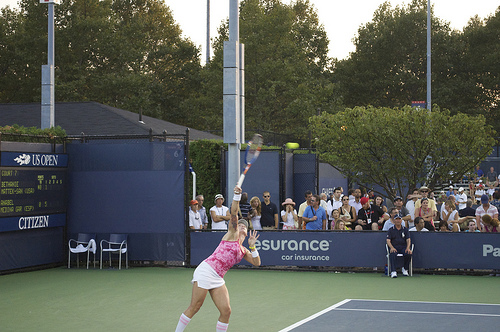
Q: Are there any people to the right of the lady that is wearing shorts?
A: Yes, there is a person to the right of the lady.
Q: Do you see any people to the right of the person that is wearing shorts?
A: Yes, there is a person to the right of the lady.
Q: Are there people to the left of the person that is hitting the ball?
A: No, the person is to the right of the lady.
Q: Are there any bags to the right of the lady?
A: No, there is a person to the right of the lady.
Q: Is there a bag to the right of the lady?
A: No, there is a person to the right of the lady.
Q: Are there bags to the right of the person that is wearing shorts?
A: No, there is a person to the right of the lady.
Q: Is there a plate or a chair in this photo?
A: Yes, there is a chair.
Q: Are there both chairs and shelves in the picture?
A: No, there is a chair but no shelves.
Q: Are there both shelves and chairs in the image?
A: No, there is a chair but no shelves.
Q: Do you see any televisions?
A: No, there are no televisions.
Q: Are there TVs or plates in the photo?
A: No, there are no TVs or plates.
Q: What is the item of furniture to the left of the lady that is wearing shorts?
A: The piece of furniture is a chair.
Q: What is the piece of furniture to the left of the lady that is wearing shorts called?
A: The piece of furniture is a chair.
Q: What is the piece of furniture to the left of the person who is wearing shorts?
A: The piece of furniture is a chair.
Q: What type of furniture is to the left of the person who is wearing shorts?
A: The piece of furniture is a chair.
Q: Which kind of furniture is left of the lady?
A: The piece of furniture is a chair.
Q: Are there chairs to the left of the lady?
A: Yes, there is a chair to the left of the lady.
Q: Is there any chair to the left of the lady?
A: Yes, there is a chair to the left of the lady.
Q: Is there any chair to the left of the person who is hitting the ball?
A: Yes, there is a chair to the left of the lady.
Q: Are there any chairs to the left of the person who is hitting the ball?
A: Yes, there is a chair to the left of the lady.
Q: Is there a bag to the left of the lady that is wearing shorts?
A: No, there is a chair to the left of the lady.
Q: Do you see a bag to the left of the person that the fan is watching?
A: No, there is a chair to the left of the lady.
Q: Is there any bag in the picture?
A: No, there are no bags.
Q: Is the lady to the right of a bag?
A: No, the lady is to the right of a chair.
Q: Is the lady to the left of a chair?
A: No, the lady is to the right of a chair.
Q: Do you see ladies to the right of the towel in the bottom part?
A: Yes, there is a lady to the right of the towel.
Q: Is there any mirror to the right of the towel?
A: No, there is a lady to the right of the towel.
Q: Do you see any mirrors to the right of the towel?
A: No, there is a lady to the right of the towel.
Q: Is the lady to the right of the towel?
A: Yes, the lady is to the right of the towel.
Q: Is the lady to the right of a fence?
A: No, the lady is to the right of the towel.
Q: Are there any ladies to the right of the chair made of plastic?
A: Yes, there is a lady to the right of the chair.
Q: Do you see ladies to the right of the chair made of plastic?
A: Yes, there is a lady to the right of the chair.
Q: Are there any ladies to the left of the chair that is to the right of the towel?
A: No, the lady is to the right of the chair.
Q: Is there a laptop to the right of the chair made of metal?
A: No, there is a lady to the right of the chair.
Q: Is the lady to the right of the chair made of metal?
A: Yes, the lady is to the right of the chair.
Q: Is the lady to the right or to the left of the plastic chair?
A: The lady is to the right of the chair.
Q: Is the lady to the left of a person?
A: Yes, the lady is to the left of a person.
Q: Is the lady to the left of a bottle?
A: No, the lady is to the left of a person.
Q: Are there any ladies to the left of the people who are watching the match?
A: Yes, there is a lady to the left of the people.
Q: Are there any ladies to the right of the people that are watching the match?
A: No, the lady is to the left of the people.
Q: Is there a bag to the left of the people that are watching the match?
A: No, there is a lady to the left of the people.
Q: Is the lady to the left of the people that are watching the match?
A: Yes, the lady is to the left of the people.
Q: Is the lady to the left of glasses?
A: No, the lady is to the left of the people.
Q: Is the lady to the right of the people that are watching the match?
A: No, the lady is to the left of the people.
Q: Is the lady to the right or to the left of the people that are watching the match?
A: The lady is to the left of the people.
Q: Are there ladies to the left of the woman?
A: Yes, there is a lady to the left of the woman.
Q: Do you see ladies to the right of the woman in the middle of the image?
A: No, the lady is to the left of the woman.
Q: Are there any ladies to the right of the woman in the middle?
A: No, the lady is to the left of the woman.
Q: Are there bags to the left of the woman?
A: No, there is a lady to the left of the woman.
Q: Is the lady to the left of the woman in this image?
A: Yes, the lady is to the left of the woman.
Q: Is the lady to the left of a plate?
A: No, the lady is to the left of the woman.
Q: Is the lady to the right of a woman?
A: No, the lady is to the left of a woman.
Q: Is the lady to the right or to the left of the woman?
A: The lady is to the left of the woman.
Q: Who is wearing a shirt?
A: The lady is wearing a shirt.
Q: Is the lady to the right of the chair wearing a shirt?
A: Yes, the lady is wearing a shirt.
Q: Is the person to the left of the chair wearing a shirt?
A: Yes, the lady is wearing a shirt.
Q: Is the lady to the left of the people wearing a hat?
A: No, the lady is wearing a shirt.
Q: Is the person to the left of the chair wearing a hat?
A: No, the lady is wearing a shirt.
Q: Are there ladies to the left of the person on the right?
A: Yes, there is a lady to the left of the person.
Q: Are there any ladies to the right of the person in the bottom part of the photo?
A: No, the lady is to the left of the person.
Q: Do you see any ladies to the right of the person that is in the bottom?
A: No, the lady is to the left of the person.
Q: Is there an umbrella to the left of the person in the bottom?
A: No, there is a lady to the left of the person.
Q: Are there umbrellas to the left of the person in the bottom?
A: No, there is a lady to the left of the person.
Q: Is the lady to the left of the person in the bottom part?
A: Yes, the lady is to the left of the person.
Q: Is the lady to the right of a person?
A: No, the lady is to the left of a person.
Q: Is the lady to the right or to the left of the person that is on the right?
A: The lady is to the left of the person.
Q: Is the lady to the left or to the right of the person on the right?
A: The lady is to the left of the person.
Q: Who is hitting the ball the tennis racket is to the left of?
A: The lady is hitting the ball.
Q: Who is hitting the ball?
A: The lady is hitting the ball.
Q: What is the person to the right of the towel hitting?
A: The lady is hitting the ball.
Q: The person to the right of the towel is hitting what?
A: The lady is hitting the ball.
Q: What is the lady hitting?
A: The lady is hitting the ball.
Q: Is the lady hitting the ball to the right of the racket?
A: Yes, the lady is hitting the ball.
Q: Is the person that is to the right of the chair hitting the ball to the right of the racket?
A: Yes, the lady is hitting the ball.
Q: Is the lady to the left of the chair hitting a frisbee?
A: No, the lady is hitting the ball.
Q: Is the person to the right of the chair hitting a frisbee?
A: No, the lady is hitting the ball.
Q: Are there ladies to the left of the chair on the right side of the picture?
A: Yes, there is a lady to the left of the chair.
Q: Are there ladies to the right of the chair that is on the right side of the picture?
A: No, the lady is to the left of the chair.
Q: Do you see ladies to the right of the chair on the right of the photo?
A: No, the lady is to the left of the chair.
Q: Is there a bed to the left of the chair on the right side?
A: No, there is a lady to the left of the chair.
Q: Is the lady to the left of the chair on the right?
A: Yes, the lady is to the left of the chair.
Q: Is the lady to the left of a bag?
A: No, the lady is to the left of the chair.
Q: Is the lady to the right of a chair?
A: No, the lady is to the left of a chair.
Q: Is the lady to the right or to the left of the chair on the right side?
A: The lady is to the left of the chair.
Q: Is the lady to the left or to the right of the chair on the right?
A: The lady is to the left of the chair.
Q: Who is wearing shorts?
A: The lady is wearing shorts.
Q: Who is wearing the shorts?
A: The lady is wearing shorts.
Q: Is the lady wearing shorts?
A: Yes, the lady is wearing shorts.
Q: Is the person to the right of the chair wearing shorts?
A: Yes, the lady is wearing shorts.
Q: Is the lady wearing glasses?
A: No, the lady is wearing shorts.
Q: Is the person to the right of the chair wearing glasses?
A: No, the lady is wearing shorts.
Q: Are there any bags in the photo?
A: No, there are no bags.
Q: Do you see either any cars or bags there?
A: No, there are no bags or cars.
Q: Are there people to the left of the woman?
A: Yes, there are people to the left of the woman.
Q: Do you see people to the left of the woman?
A: Yes, there are people to the left of the woman.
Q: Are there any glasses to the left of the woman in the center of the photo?
A: No, there are people to the left of the woman.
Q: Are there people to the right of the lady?
A: Yes, there are people to the right of the lady.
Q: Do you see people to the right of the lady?
A: Yes, there are people to the right of the lady.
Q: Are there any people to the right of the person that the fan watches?
A: Yes, there are people to the right of the lady.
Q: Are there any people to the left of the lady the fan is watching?
A: No, the people are to the right of the lady.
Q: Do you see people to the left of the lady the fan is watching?
A: No, the people are to the right of the lady.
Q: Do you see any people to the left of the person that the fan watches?
A: No, the people are to the right of the lady.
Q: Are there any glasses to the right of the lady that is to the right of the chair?
A: No, there are people to the right of the lady.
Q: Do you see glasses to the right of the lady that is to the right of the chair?
A: No, there are people to the right of the lady.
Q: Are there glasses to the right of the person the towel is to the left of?
A: No, there are people to the right of the lady.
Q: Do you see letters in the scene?
A: Yes, there are letters.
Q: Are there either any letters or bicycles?
A: Yes, there are letters.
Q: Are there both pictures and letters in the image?
A: No, there are letters but no pictures.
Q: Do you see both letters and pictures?
A: No, there are letters but no pictures.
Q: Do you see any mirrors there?
A: No, there are no mirrors.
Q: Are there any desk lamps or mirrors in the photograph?
A: No, there are no mirrors or desk lamps.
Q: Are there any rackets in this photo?
A: Yes, there is a racket.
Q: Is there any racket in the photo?
A: Yes, there is a racket.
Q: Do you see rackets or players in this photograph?
A: Yes, there is a racket.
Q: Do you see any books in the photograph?
A: No, there are no books.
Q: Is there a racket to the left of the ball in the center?
A: Yes, there is a racket to the left of the ball.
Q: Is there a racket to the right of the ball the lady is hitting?
A: No, the racket is to the left of the ball.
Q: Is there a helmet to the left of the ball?
A: No, there is a racket to the left of the ball.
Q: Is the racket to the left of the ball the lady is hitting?
A: Yes, the racket is to the left of the ball.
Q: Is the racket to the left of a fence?
A: No, the racket is to the left of the ball.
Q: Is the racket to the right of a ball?
A: No, the racket is to the left of a ball.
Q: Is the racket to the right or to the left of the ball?
A: The racket is to the left of the ball.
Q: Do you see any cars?
A: No, there are no cars.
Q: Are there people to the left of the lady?
A: No, the person is to the right of the lady.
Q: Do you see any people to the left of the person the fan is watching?
A: No, the person is to the right of the lady.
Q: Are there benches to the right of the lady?
A: No, there is a person to the right of the lady.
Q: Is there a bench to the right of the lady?
A: No, there is a person to the right of the lady.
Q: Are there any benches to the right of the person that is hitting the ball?
A: No, there is a person to the right of the lady.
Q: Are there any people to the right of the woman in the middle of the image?
A: Yes, there is a person to the right of the woman.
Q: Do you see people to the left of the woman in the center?
A: No, the person is to the right of the woman.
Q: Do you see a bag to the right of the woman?
A: No, there is a person to the right of the woman.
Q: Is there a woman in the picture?
A: Yes, there is a woman.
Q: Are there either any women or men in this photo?
A: Yes, there is a woman.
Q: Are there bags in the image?
A: No, there are no bags.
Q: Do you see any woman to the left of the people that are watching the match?
A: Yes, there is a woman to the left of the people.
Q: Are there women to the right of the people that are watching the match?
A: No, the woman is to the left of the people.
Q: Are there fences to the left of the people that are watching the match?
A: No, there is a woman to the left of the people.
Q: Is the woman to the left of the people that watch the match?
A: Yes, the woman is to the left of the people.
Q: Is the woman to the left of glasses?
A: No, the woman is to the left of the people.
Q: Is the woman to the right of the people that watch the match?
A: No, the woman is to the left of the people.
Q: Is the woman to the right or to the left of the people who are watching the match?
A: The woman is to the left of the people.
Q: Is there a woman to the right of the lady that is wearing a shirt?
A: Yes, there is a woman to the right of the lady.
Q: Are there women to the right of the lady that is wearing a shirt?
A: Yes, there is a woman to the right of the lady.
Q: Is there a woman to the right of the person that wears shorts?
A: Yes, there is a woman to the right of the lady.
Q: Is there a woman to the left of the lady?
A: No, the woman is to the right of the lady.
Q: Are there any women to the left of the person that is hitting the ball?
A: No, the woman is to the right of the lady.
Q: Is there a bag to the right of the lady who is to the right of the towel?
A: No, there is a woman to the right of the lady.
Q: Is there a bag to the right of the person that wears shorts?
A: No, there is a woman to the right of the lady.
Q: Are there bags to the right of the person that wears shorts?
A: No, there is a woman to the right of the lady.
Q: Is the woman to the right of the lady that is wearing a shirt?
A: Yes, the woman is to the right of the lady.